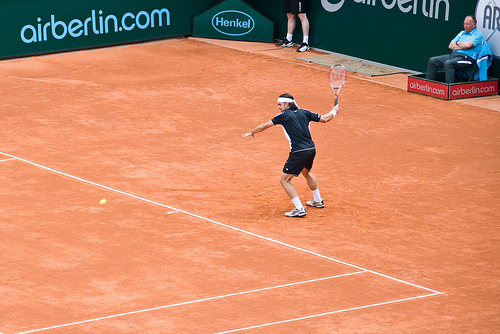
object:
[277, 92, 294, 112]
player's head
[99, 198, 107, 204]
ball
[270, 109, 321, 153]
shirt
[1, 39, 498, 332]
dirt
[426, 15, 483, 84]
judge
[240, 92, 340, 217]
athlete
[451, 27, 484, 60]
shirt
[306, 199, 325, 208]
shoe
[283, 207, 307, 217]
shoe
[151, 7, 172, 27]
blue letter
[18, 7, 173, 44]
ad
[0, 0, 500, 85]
wall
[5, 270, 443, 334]
line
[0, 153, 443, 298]
line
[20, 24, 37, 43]
blueletter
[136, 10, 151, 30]
blueletter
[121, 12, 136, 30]
blueletter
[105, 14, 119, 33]
blueletter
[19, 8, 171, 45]
letter blue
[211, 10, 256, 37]
letter blue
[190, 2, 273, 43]
advertisement wall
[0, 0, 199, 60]
advertisement wall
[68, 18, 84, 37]
letter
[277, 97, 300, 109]
headband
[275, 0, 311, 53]
man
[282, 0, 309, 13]
shorts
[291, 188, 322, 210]
socks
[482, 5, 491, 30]
blue letter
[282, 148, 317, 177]
black shorts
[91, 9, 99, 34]
blue letter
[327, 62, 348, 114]
racket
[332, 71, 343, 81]
w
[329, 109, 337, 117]
wristband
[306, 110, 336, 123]
arm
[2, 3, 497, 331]
air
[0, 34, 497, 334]
court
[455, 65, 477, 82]
chair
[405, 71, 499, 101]
box